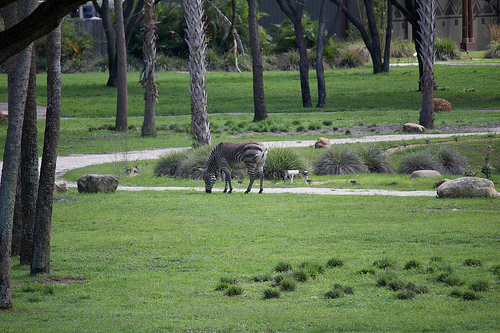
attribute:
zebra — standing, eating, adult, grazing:
[193, 138, 268, 193]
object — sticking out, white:
[283, 165, 300, 182]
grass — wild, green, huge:
[71, 135, 497, 191]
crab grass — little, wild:
[215, 246, 353, 315]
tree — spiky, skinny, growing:
[406, 4, 447, 133]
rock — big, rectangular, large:
[77, 168, 121, 195]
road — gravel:
[2, 130, 456, 191]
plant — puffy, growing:
[149, 146, 187, 177]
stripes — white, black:
[219, 143, 247, 163]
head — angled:
[196, 163, 218, 196]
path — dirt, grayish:
[68, 175, 439, 208]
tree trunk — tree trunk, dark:
[358, 21, 392, 71]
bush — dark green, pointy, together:
[158, 146, 215, 178]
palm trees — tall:
[132, 2, 220, 141]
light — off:
[409, 49, 419, 65]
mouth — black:
[203, 187, 214, 195]